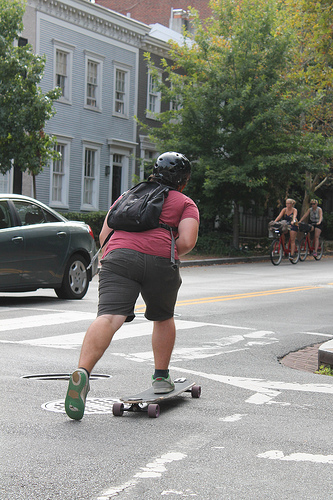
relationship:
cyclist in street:
[270, 193, 327, 266] [205, 269, 316, 317]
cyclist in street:
[300, 196, 324, 260] [205, 269, 316, 317]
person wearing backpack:
[62, 151, 198, 419] [106, 174, 180, 233]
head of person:
[144, 146, 196, 201] [62, 151, 198, 419]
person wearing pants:
[62, 151, 198, 419] [98, 247, 180, 324]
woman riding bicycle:
[276, 200, 297, 258] [267, 221, 298, 266]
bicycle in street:
[267, 221, 298, 266] [0, 255, 333, 425]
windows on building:
[50, 37, 132, 120] [0, 0, 209, 216]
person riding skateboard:
[62, 137, 198, 419] [107, 375, 207, 423]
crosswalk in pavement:
[1, 298, 323, 389] [0, 296, 330, 495]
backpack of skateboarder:
[107, 184, 161, 230] [62, 144, 200, 408]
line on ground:
[22, 316, 206, 348] [2, 256, 330, 498]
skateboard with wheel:
[119, 357, 232, 430] [188, 383, 207, 402]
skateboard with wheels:
[119, 357, 232, 430] [148, 404, 163, 419]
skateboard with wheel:
[119, 357, 232, 430] [110, 401, 126, 421]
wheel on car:
[50, 251, 112, 314] [2, 182, 129, 289]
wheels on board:
[148, 404, 163, 419] [110, 348, 230, 439]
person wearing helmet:
[62, 137, 198, 419] [139, 148, 200, 188]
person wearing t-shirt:
[62, 151, 198, 419] [101, 185, 199, 259]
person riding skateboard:
[62, 137, 198, 419] [106, 372, 200, 418]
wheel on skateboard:
[61, 256, 94, 309] [111, 375, 200, 417]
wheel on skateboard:
[183, 384, 208, 400] [109, 375, 204, 420]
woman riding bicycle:
[276, 200, 297, 258] [264, 221, 302, 264]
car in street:
[1, 191, 108, 299] [3, 253, 327, 498]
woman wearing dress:
[276, 200, 297, 258] [282, 211, 298, 232]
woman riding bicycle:
[276, 200, 297, 258] [269, 228, 299, 263]